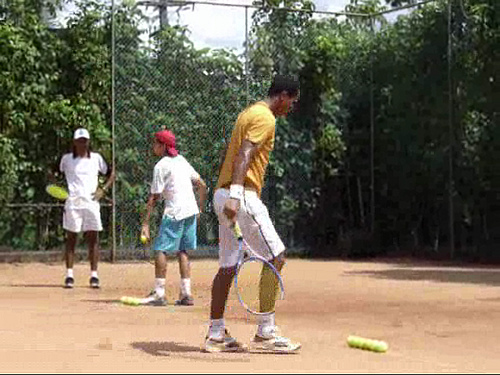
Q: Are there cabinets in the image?
A: No, there are no cabinets.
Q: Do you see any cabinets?
A: No, there are no cabinets.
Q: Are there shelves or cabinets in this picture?
A: No, there are no cabinets or shelves.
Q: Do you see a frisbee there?
A: No, there are no frisbees.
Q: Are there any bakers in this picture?
A: No, there are no bakers.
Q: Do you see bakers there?
A: No, there are no bakers.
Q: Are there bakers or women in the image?
A: No, there are no bakers or women.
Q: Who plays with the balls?
A: The man plays with the balls.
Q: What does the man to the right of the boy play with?
A: The man plays with balls.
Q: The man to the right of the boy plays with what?
A: The man plays with balls.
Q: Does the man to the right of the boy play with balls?
A: Yes, the man plays with balls.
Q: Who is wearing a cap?
A: The man is wearing a cap.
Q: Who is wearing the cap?
A: The man is wearing a cap.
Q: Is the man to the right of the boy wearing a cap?
A: Yes, the man is wearing a cap.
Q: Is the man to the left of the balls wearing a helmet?
A: No, the man is wearing a cap.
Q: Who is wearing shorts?
A: The man is wearing shorts.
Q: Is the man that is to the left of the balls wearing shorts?
A: Yes, the man is wearing shorts.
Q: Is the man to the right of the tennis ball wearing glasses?
A: No, the man is wearing shorts.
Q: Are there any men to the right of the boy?
A: Yes, there is a man to the right of the boy.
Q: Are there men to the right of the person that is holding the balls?
A: Yes, there is a man to the right of the boy.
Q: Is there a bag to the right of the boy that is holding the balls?
A: No, there is a man to the right of the boy.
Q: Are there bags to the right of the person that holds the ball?
A: No, there is a man to the right of the boy.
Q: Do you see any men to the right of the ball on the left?
A: Yes, there is a man to the right of the ball.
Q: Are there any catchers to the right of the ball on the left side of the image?
A: No, there is a man to the right of the ball.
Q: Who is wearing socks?
A: The man is wearing socks.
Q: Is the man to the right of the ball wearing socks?
A: Yes, the man is wearing socks.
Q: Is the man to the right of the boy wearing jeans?
A: No, the man is wearing socks.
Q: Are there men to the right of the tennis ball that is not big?
A: Yes, there is a man to the right of the tennis ball.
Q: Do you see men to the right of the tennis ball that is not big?
A: Yes, there is a man to the right of the tennis ball.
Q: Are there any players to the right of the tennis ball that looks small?
A: No, there is a man to the right of the tennis ball.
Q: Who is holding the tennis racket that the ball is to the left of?
A: The man is holding the racket.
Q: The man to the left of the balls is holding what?
A: The man is holding the racket.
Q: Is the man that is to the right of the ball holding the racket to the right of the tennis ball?
A: Yes, the man is holding the racket.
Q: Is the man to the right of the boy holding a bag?
A: No, the man is holding the racket.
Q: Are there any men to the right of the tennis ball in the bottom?
A: Yes, there is a man to the right of the tennis ball.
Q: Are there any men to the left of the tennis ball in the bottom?
A: No, the man is to the right of the tennis ball.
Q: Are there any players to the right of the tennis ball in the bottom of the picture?
A: No, there is a man to the right of the tennis ball.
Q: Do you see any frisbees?
A: No, there are no frisbees.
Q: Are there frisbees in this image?
A: No, there are no frisbees.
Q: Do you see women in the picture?
A: No, there are no women.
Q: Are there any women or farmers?
A: No, there are no women or farmers.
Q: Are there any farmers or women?
A: No, there are no women or farmers.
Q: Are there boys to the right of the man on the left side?
A: Yes, there is a boy to the right of the man.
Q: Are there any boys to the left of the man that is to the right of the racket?
A: No, the boy is to the right of the man.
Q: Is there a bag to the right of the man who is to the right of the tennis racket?
A: No, there is a boy to the right of the man.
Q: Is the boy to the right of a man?
A: Yes, the boy is to the right of a man.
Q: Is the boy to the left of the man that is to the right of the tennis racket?
A: No, the boy is to the right of the man.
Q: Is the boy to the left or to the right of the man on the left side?
A: The boy is to the right of the man.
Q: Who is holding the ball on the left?
A: The boy is holding the ball.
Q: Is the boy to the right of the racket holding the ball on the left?
A: Yes, the boy is holding the ball.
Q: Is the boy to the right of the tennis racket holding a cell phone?
A: No, the boy is holding the ball.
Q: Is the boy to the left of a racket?
A: Yes, the boy is to the left of a racket.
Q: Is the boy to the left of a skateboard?
A: No, the boy is to the left of a racket.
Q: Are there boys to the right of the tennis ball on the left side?
A: Yes, there is a boy to the right of the tennis ball.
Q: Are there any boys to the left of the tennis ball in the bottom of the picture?
A: No, the boy is to the right of the tennis ball.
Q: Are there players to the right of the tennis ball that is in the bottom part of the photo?
A: No, there is a boy to the right of the tennis ball.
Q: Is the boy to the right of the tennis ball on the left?
A: Yes, the boy is to the right of the tennis ball.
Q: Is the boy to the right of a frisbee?
A: No, the boy is to the right of the tennis ball.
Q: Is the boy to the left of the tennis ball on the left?
A: No, the boy is to the right of the tennis ball.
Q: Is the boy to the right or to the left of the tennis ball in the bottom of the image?
A: The boy is to the right of the tennis ball.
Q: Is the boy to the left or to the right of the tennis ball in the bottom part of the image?
A: The boy is to the right of the tennis ball.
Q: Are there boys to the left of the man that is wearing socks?
A: Yes, there is a boy to the left of the man.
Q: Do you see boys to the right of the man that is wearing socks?
A: No, the boy is to the left of the man.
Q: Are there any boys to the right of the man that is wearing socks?
A: No, the boy is to the left of the man.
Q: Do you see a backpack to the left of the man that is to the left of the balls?
A: No, there is a boy to the left of the man.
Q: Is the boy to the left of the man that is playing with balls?
A: Yes, the boy is to the left of the man.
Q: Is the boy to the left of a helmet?
A: No, the boy is to the left of the man.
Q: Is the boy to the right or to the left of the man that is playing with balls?
A: The boy is to the left of the man.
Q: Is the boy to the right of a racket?
A: Yes, the boy is to the right of a racket.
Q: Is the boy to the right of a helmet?
A: No, the boy is to the right of a racket.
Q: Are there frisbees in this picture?
A: No, there are no frisbees.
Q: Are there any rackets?
A: Yes, there is a racket.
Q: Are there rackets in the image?
A: Yes, there is a racket.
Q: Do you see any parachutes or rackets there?
A: Yes, there is a racket.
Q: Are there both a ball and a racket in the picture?
A: Yes, there are both a racket and a ball.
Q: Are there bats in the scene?
A: No, there are no bats.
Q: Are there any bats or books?
A: No, there are no bats or books.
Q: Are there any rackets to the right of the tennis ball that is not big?
A: Yes, there is a racket to the right of the tennis ball.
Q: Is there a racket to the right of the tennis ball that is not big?
A: Yes, there is a racket to the right of the tennis ball.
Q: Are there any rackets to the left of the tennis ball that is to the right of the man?
A: No, the racket is to the right of the tennis ball.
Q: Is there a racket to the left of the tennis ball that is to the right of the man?
A: No, the racket is to the right of the tennis ball.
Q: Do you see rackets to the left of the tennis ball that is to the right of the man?
A: No, the racket is to the right of the tennis ball.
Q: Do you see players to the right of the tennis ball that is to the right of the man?
A: No, there is a racket to the right of the tennis ball.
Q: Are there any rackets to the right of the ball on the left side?
A: Yes, there is a racket to the right of the ball.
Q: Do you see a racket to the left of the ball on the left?
A: No, the racket is to the right of the ball.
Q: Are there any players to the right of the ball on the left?
A: No, there is a racket to the right of the ball.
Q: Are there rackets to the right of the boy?
A: Yes, there is a racket to the right of the boy.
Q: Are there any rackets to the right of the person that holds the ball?
A: Yes, there is a racket to the right of the boy.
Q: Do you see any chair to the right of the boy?
A: No, there is a racket to the right of the boy.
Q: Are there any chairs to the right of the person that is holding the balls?
A: No, there is a racket to the right of the boy.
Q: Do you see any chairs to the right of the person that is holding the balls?
A: No, there is a racket to the right of the boy.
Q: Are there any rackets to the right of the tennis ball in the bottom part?
A: Yes, there is a racket to the right of the tennis ball.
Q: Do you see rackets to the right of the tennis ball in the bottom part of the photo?
A: Yes, there is a racket to the right of the tennis ball.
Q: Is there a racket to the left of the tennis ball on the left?
A: No, the racket is to the right of the tennis ball.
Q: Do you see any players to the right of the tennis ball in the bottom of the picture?
A: No, there is a racket to the right of the tennis ball.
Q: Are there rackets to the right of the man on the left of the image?
A: Yes, there is a racket to the right of the man.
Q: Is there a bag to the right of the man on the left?
A: No, there is a racket to the right of the man.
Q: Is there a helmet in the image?
A: No, there are no helmets.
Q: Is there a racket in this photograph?
A: Yes, there is a racket.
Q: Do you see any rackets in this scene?
A: Yes, there is a racket.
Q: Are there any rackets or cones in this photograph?
A: Yes, there is a racket.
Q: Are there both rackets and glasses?
A: No, there is a racket but no glasses.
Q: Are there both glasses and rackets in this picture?
A: No, there is a racket but no glasses.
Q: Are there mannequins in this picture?
A: No, there are no mannequins.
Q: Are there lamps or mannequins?
A: No, there are no mannequins or lamps.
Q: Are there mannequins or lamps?
A: No, there are no mannequins or lamps.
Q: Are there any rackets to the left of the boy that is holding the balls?
A: Yes, there is a racket to the left of the boy.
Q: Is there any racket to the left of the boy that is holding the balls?
A: Yes, there is a racket to the left of the boy.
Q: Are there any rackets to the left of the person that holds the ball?
A: Yes, there is a racket to the left of the boy.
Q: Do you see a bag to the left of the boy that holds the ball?
A: No, there is a racket to the left of the boy.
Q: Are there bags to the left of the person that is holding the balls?
A: No, there is a racket to the left of the boy.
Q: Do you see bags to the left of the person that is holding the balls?
A: No, there is a racket to the left of the boy.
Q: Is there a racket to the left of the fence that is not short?
A: Yes, there is a racket to the left of the fence.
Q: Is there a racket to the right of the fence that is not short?
A: No, the racket is to the left of the fence.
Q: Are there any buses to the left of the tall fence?
A: No, there is a racket to the left of the fence.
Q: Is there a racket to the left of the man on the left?
A: Yes, there is a racket to the left of the man.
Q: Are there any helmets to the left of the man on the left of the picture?
A: No, there is a racket to the left of the man.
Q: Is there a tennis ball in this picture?
A: Yes, there is a tennis ball.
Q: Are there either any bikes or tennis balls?
A: Yes, there is a tennis ball.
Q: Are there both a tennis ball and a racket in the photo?
A: Yes, there are both a tennis ball and a racket.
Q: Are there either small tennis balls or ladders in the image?
A: Yes, there is a small tennis ball.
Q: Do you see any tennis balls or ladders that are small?
A: Yes, the tennis ball is small.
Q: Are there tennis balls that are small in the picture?
A: Yes, there is a small tennis ball.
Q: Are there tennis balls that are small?
A: Yes, there is a tennis ball that is small.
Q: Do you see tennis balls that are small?
A: Yes, there is a tennis ball that is small.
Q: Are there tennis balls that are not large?
A: Yes, there is a small tennis ball.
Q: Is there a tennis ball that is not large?
A: Yes, there is a small tennis ball.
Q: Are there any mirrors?
A: No, there are no mirrors.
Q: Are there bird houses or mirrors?
A: No, there are no mirrors or bird houses.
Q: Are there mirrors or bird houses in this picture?
A: No, there are no mirrors or bird houses.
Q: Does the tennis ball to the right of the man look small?
A: Yes, the tennis ball is small.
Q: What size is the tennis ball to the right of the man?
A: The tennis ball is small.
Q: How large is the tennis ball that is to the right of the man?
A: The tennis ball is small.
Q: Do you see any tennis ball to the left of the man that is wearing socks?
A: Yes, there is a tennis ball to the left of the man.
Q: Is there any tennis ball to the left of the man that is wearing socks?
A: Yes, there is a tennis ball to the left of the man.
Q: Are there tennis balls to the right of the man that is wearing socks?
A: No, the tennis ball is to the left of the man.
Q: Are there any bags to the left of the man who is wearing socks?
A: No, there is a tennis ball to the left of the man.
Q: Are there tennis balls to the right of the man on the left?
A: Yes, there is a tennis ball to the right of the man.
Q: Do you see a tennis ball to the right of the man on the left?
A: Yes, there is a tennis ball to the right of the man.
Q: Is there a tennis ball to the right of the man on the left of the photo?
A: Yes, there is a tennis ball to the right of the man.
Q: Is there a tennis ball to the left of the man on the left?
A: No, the tennis ball is to the right of the man.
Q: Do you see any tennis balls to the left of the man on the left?
A: No, the tennis ball is to the right of the man.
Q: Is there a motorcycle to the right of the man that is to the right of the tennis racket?
A: No, there is a tennis ball to the right of the man.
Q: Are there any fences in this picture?
A: Yes, there is a fence.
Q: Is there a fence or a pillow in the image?
A: Yes, there is a fence.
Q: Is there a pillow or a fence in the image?
A: Yes, there is a fence.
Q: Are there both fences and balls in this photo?
A: Yes, there are both a fence and a ball.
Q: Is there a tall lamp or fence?
A: Yes, there is a tall fence.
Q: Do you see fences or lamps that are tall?
A: Yes, the fence is tall.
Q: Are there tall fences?
A: Yes, there is a tall fence.